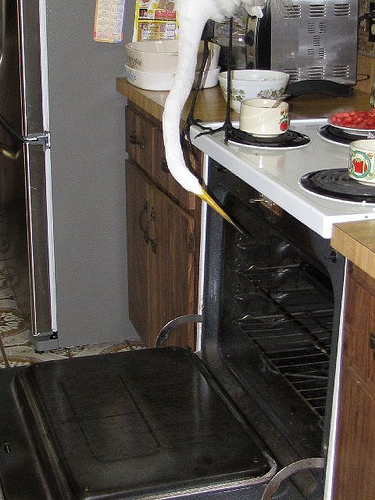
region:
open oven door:
[0, 351, 259, 498]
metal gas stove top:
[190, 83, 373, 222]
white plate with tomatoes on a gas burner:
[325, 88, 374, 134]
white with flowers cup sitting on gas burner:
[229, 91, 306, 160]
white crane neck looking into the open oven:
[155, 0, 258, 243]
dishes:
[119, 33, 224, 95]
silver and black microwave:
[209, 0, 372, 90]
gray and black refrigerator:
[0, 1, 145, 339]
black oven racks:
[217, 190, 336, 465]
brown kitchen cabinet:
[107, 75, 211, 351]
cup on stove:
[217, 93, 297, 150]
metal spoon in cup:
[248, 78, 303, 138]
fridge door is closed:
[9, 12, 63, 346]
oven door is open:
[20, 335, 302, 493]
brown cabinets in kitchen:
[105, 102, 207, 351]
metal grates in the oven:
[239, 260, 330, 406]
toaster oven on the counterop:
[242, 1, 365, 88]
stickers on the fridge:
[84, 0, 197, 47]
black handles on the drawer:
[126, 132, 184, 180]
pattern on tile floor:
[0, 313, 57, 359]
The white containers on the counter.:
[118, 36, 223, 85]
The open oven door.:
[1, 353, 279, 493]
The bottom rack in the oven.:
[238, 312, 340, 413]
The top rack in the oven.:
[242, 247, 338, 350]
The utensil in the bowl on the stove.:
[262, 92, 292, 107]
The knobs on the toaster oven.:
[239, 22, 257, 70]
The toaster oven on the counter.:
[215, 9, 353, 88]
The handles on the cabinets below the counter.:
[138, 198, 168, 250]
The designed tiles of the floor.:
[5, 310, 45, 365]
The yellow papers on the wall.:
[88, 3, 185, 48]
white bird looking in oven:
[147, 0, 260, 229]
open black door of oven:
[2, 348, 258, 496]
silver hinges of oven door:
[148, 306, 321, 493]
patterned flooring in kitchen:
[2, 262, 136, 363]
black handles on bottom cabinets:
[125, 121, 176, 251]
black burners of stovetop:
[225, 97, 373, 217]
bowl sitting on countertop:
[218, 58, 278, 115]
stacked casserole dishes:
[116, 29, 221, 87]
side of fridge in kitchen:
[3, 4, 120, 339]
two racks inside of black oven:
[222, 211, 328, 427]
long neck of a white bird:
[150, 9, 251, 238]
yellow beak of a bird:
[191, 181, 240, 234]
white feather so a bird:
[80, 4, 240, 179]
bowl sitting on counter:
[215, 61, 303, 144]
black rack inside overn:
[259, 314, 331, 405]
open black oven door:
[0, 342, 263, 498]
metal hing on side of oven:
[270, 443, 326, 499]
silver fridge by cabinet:
[0, 74, 132, 343]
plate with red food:
[327, 108, 369, 136]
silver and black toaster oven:
[189, 0, 364, 94]